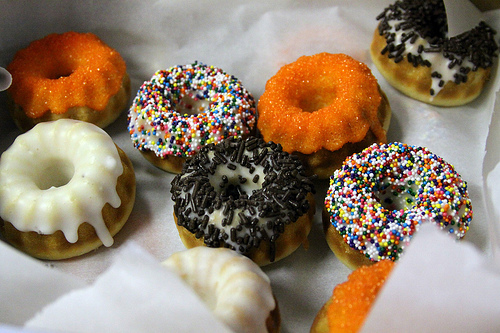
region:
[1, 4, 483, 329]
several tasty donuts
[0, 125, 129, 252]
this is a white topping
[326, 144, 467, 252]
a donut with confetti on it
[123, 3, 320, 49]
a pieces of bakery paper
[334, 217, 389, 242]
small differents colors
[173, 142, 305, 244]
a donut coverd with chocolate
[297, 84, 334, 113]
the center hole of the donut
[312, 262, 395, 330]
part of a donut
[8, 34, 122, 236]
a white and orange toppings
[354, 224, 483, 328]
a piece of paper covering part of the donuts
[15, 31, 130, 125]
doughnut with orange frosting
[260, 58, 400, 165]
doughnut with orange frosting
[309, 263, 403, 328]
doughnut with orange frosting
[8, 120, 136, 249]
doughnut with white frosting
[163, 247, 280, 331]
doughnut with white frosting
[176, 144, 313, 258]
doughnut with white frosting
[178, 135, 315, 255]
doughnut with chocolate sprinkles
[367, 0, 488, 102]
doughnut with chocolate sprinkles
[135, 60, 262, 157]
doughnut with rainbow sprinkles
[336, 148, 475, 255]
doughnut with rainbow sprinkles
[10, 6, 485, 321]
doughnuts on white paper curled over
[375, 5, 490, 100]
browned doughnut under white icing and chocolate sprinkles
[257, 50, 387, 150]
sparkly orange icing over doughnut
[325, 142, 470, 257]
colorful round and hard sprinkles on top of doughnut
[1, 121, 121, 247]
white icing in frozen drips over side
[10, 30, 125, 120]
hole in the middle of orange and yellow doughnut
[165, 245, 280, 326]
exposed ridges on semicircle of doughnut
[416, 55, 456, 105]
white point over edge of doughnut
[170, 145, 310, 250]
hole covered with icing and black sprinkles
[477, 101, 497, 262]
torn edge of white paper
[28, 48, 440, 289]
these are some donuts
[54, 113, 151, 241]
this is a lemon donut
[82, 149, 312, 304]
the donuts are mini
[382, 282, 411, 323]
this is parchment paper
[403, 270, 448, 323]
the paper is white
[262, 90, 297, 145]
the frosting is orange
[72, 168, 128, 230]
the frosting is dripping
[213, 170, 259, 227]
these are spinkles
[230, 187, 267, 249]
the sprinkles are chocolate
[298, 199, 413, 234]
these are some nonparells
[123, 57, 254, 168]
donut covered with sprinkles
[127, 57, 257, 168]
colorful donut on a paper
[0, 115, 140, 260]
white frosting on a donut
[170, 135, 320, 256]
white frosted donut covered in black sprinkles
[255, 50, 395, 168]
donut with an orange topping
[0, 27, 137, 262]
two donuts on a white paper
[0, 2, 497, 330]
small donuts on a white paper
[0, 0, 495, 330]
small colorful donuts on a white paper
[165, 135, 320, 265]
donut topped with dark colored sprinkles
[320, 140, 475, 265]
donut covered in many round colorful sprinkles